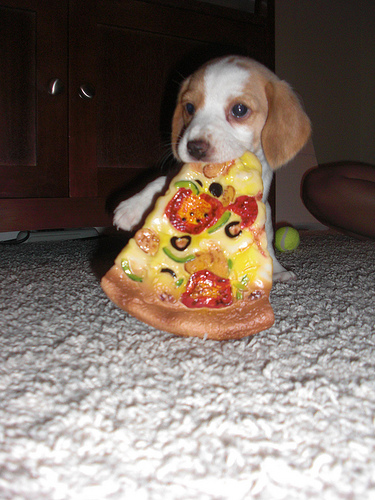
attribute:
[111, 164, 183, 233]
paw — airborne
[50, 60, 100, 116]
silver knob — round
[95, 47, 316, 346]
puppy — brown and white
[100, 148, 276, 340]
dog toy — pizza shaped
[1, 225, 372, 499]
carpet — white and brown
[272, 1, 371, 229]
wall — white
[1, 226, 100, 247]
power strip — gray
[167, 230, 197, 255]
olive — sliced, black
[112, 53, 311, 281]
puppy — white and brown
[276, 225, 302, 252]
ball — yellow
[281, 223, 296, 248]
ball — yellow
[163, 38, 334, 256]
puppy — white and brown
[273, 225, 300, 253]
ball — green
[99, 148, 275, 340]
pizza — large, sliced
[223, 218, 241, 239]
olive slice — black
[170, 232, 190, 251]
olive slice — black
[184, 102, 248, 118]
eyes — blue